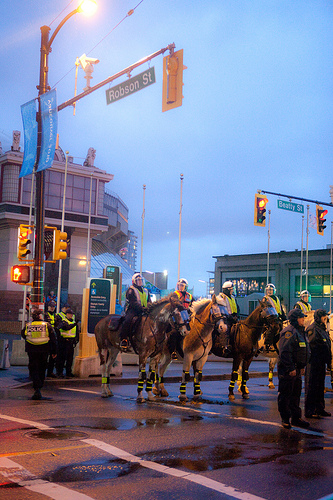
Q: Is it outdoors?
A: Yes, it is outdoors.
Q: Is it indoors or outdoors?
A: It is outdoors.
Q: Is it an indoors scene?
A: No, it is outdoors.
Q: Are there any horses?
A: Yes, there is a horse.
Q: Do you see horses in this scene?
A: Yes, there is a horse.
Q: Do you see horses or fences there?
A: Yes, there is a horse.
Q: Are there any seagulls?
A: No, there are no seagulls.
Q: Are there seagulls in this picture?
A: No, there are no seagulls.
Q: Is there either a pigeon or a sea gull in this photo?
A: No, there are no seagulls or pigeons.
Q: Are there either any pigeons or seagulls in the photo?
A: No, there are no seagulls or pigeons.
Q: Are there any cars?
A: No, there are no cars.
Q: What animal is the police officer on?
A: The police officer is on the horse.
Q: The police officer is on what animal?
A: The police officer is on the horse.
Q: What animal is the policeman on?
A: The police officer is on the horse.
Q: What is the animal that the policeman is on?
A: The animal is a horse.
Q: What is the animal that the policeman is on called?
A: The animal is a horse.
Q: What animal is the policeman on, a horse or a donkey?
A: The policeman is on a horse.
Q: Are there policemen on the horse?
A: Yes, there is a policeman on the horse.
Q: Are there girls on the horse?
A: No, there is a policeman on the horse.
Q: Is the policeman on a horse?
A: Yes, the policeman is on a horse.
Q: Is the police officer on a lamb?
A: No, the police officer is on a horse.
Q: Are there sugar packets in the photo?
A: No, there are no sugar packets.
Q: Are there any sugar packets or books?
A: No, there are no sugar packets or books.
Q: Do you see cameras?
A: Yes, there is a camera.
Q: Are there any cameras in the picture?
A: Yes, there is a camera.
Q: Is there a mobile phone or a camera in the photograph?
A: Yes, there is a camera.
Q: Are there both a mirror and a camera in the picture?
A: No, there is a camera but no mirrors.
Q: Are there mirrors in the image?
A: No, there are no mirrors.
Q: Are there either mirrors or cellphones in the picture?
A: No, there are no mirrors or cellphones.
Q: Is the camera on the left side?
A: Yes, the camera is on the left of the image.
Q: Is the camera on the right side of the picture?
A: No, the camera is on the left of the image.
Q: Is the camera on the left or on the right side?
A: The camera is on the left of the image.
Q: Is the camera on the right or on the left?
A: The camera is on the left of the image.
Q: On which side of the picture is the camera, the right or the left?
A: The camera is on the left of the image.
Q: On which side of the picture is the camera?
A: The camera is on the left of the image.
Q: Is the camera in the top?
A: Yes, the camera is in the top of the image.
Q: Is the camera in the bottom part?
A: No, the camera is in the top of the image.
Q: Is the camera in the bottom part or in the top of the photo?
A: The camera is in the top of the image.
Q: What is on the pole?
A: The camera is on the pole.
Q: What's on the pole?
A: The camera is on the pole.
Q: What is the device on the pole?
A: The device is a camera.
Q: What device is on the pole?
A: The device is a camera.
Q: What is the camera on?
A: The camera is on the pole.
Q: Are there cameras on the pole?
A: Yes, there is a camera on the pole.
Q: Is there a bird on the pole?
A: No, there is a camera on the pole.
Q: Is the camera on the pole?
A: Yes, the camera is on the pole.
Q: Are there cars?
A: No, there are no cars.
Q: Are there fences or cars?
A: No, there are no cars or fences.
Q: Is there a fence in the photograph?
A: No, there are no fences.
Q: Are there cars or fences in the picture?
A: No, there are no fences or cars.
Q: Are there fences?
A: No, there are no fences.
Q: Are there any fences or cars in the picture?
A: No, there are no fences or cars.